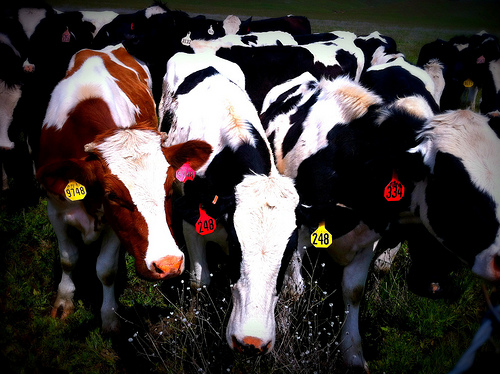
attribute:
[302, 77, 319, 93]
spot — small, black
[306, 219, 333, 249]
tag — yellow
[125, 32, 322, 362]
cow — black and white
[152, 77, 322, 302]
cow — black and white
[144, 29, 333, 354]
cow — black and white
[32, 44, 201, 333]
cow — black and white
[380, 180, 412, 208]
tag — red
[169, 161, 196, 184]
tag — red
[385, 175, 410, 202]
tag — red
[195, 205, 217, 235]
tag — red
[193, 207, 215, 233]
redtag — red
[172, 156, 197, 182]
redtag — red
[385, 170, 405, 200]
redtag — red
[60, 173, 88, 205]
ear tag — yellow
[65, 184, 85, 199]
number — 9748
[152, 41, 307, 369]
cow — black and white, brown and white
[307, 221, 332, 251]
ear tag — yellow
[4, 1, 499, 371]
cows — tagged